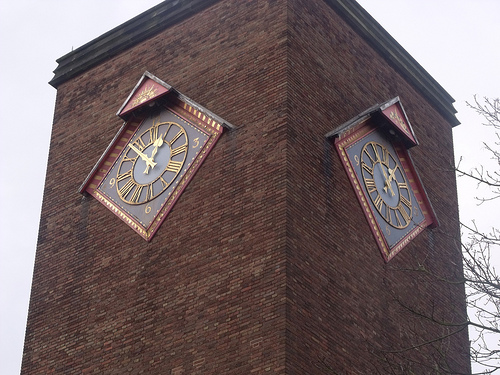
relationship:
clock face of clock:
[95, 105, 211, 230] [52, 73, 241, 250]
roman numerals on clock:
[115, 122, 189, 204] [96, 114, 236, 221]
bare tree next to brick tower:
[377, 94, 500, 375] [18, 0, 472, 372]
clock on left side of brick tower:
[83, 71, 225, 241] [18, 0, 472, 372]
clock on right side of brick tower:
[342, 124, 425, 252] [18, 0, 472, 372]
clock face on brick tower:
[101, 118, 191, 205] [18, 0, 472, 372]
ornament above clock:
[116, 69, 177, 124] [76, 68, 236, 241]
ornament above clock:
[369, 93, 418, 151] [322, 96, 437, 264]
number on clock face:
[141, 201, 156, 219] [95, 110, 194, 210]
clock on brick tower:
[342, 124, 425, 252] [18, 0, 472, 372]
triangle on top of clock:
[114, 68, 178, 120] [78, 95, 234, 242]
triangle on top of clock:
[362, 94, 419, 148] [324, 115, 441, 262]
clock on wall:
[95, 107, 210, 230] [38, 29, 281, 299]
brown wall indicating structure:
[20, 3, 285, 371] [19, 8, 465, 370]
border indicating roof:
[88, 25, 126, 60] [37, 2, 467, 130]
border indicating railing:
[88, 25, 126, 60] [34, 2, 466, 133]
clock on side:
[359, 132, 416, 232] [285, 11, 471, 364]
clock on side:
[95, 107, 210, 230] [39, 23, 272, 351]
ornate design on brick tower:
[80, 70, 233, 242] [18, 0, 472, 372]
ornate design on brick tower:
[325, 97, 440, 261] [18, 0, 472, 372]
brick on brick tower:
[57, 201, 96, 252] [18, 0, 472, 372]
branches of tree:
[449, 91, 498, 374] [430, 70, 480, 361]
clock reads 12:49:
[342, 124, 425, 252] [365, 139, 405, 200]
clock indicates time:
[95, 107, 210, 230] [330, 95, 438, 257]